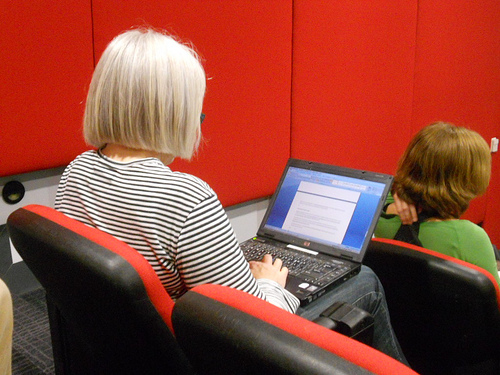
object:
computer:
[226, 156, 396, 311]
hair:
[79, 25, 210, 165]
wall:
[0, 0, 499, 260]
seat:
[4, 196, 184, 374]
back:
[357, 237, 500, 374]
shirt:
[368, 189, 498, 284]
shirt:
[50, 143, 301, 320]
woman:
[44, 20, 413, 367]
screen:
[259, 163, 385, 254]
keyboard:
[235, 231, 357, 289]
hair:
[384, 122, 495, 221]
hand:
[387, 191, 423, 228]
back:
[366, 191, 499, 284]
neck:
[94, 140, 160, 164]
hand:
[244, 251, 291, 291]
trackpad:
[246, 250, 294, 291]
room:
[1, 0, 500, 374]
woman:
[367, 121, 499, 292]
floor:
[9, 278, 54, 374]